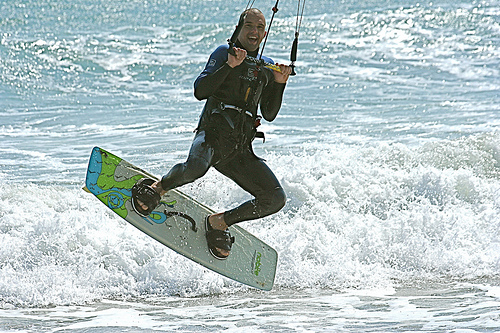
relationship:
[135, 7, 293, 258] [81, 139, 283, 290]
man riding board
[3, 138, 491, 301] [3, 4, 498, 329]
waves in water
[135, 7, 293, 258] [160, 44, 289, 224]
man has wetsuit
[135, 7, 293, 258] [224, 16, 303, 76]
man holding handle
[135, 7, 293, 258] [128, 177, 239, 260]
man has feet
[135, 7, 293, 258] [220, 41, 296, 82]
man has hands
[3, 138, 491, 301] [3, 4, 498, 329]
waves in ocean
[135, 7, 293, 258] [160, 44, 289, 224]
man in wetsuit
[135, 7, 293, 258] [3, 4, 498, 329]
man enjoying ocean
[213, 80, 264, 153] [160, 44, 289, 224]
safety straps on wetsuit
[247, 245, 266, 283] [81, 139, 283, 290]
brand name on board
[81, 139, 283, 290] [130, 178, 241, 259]
board has footstraps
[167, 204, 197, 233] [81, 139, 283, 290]
handle on board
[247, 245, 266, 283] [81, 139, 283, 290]
letters on board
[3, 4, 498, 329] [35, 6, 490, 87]
ocean has foam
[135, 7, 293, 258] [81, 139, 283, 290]
man on board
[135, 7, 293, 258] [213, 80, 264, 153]
man wearing harness